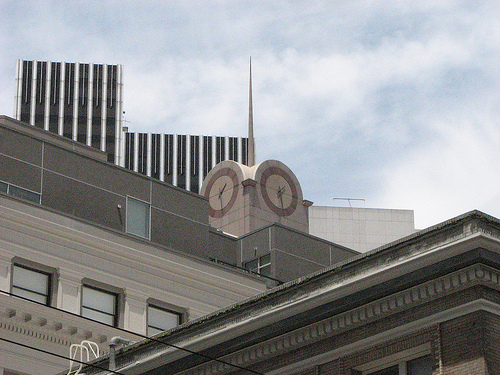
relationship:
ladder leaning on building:
[70, 343, 97, 372] [170, 327, 292, 352]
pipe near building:
[108, 339, 120, 372] [170, 327, 292, 352]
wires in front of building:
[11, 300, 72, 312] [170, 327, 292, 352]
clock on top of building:
[206, 166, 248, 218] [170, 327, 292, 352]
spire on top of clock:
[244, 55, 257, 161] [206, 166, 248, 218]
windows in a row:
[15, 266, 49, 296] [8, 255, 172, 335]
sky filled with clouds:
[417, 79, 448, 117] [277, 31, 385, 94]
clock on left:
[206, 166, 248, 218] [218, 185, 229, 209]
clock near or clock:
[206, 166, 248, 218] [257, 162, 300, 215]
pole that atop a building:
[244, 55, 257, 161] [170, 327, 292, 352]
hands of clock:
[218, 185, 229, 209] [206, 166, 248, 218]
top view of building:
[21, 53, 134, 86] [170, 327, 292, 352]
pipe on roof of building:
[108, 339, 120, 372] [170, 327, 292, 352]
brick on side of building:
[454, 326, 471, 347] [170, 327, 292, 352]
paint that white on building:
[49, 227, 106, 250] [170, 327, 292, 352]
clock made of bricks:
[257, 162, 300, 215] [246, 211, 261, 225]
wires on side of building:
[11, 300, 72, 312] [170, 327, 292, 352]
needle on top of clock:
[244, 55, 257, 161] [206, 166, 248, 218]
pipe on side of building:
[108, 339, 120, 372] [170, 327, 292, 352]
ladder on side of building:
[70, 343, 97, 372] [170, 327, 292, 352]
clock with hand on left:
[206, 166, 248, 218] [218, 185, 229, 209]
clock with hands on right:
[206, 166, 248, 218] [277, 188, 288, 208]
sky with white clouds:
[417, 79, 448, 117] [277, 31, 385, 94]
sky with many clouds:
[417, 79, 448, 117] [277, 31, 385, 94]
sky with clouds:
[417, 79, 448, 117] [277, 31, 385, 94]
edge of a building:
[162, 181, 200, 195] [170, 327, 292, 352]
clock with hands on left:
[206, 166, 248, 218] [218, 185, 229, 209]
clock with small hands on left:
[206, 166, 248, 218] [218, 185, 229, 209]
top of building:
[21, 53, 134, 86] [170, 327, 292, 352]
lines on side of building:
[70, 66, 83, 133] [170, 327, 292, 352]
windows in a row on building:
[15, 266, 49, 296] [170, 327, 292, 352]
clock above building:
[206, 166, 248, 218] [170, 327, 292, 352]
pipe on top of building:
[108, 339, 120, 372] [170, 327, 292, 352]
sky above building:
[417, 79, 448, 117] [170, 327, 292, 352]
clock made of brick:
[206, 166, 248, 218] [229, 219, 246, 227]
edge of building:
[162, 181, 200, 195] [170, 327, 292, 352]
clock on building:
[206, 166, 248, 218] [1, 105, 485, 365]